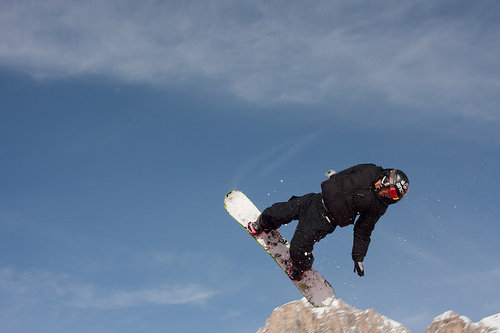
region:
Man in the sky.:
[183, 130, 461, 310]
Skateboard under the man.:
[220, 159, 327, 324]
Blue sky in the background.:
[41, 112, 293, 293]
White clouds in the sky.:
[2, 207, 194, 322]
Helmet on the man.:
[382, 155, 447, 219]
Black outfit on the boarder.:
[243, 123, 425, 303]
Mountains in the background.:
[234, 277, 422, 330]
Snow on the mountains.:
[293, 280, 414, 330]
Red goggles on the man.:
[380, 177, 419, 217]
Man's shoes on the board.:
[249, 210, 313, 302]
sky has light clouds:
[0, 0, 497, 330]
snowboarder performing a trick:
[248, 163, 413, 288]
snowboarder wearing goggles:
[246, 164, 411, 285]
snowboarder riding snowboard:
[218, 155, 408, 303]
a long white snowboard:
[213, 190, 334, 305]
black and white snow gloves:
[354, 259, 366, 274]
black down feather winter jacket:
[317, 162, 387, 257]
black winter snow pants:
[255, 181, 335, 266]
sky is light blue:
[0, 0, 492, 330]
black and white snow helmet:
[380, 165, 406, 197]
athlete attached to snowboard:
[186, 85, 411, 316]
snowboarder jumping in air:
[201, 130, 433, 315]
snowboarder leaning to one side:
[167, 130, 422, 305]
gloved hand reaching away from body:
[325, 241, 391, 297]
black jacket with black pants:
[185, 86, 425, 288]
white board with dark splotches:
[220, 180, 350, 310]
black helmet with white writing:
[355, 140, 415, 216]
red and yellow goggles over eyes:
[371, 141, 406, 221]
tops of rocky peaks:
[240, 285, 475, 325]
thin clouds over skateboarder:
[82, 25, 472, 208]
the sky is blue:
[73, 114, 160, 196]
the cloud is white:
[45, 21, 247, 75]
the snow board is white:
[211, 174, 357, 314]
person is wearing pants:
[245, 180, 365, 277]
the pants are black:
[249, 192, 354, 284]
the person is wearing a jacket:
[318, 142, 392, 262]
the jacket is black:
[322, 147, 397, 272]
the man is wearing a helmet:
[366, 138, 424, 216]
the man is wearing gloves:
[312, 152, 389, 293]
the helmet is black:
[378, 159, 426, 216]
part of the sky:
[46, 57, 183, 182]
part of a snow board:
[224, 196, 250, 226]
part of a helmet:
[393, 172, 411, 197]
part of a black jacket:
[328, 187, 358, 234]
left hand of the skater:
[351, 257, 366, 283]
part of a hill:
[341, 305, 378, 322]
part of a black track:
[288, 208, 314, 249]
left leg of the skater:
[286, 230, 309, 276]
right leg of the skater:
[256, 200, 288, 231]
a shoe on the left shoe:
[286, 262, 301, 282]